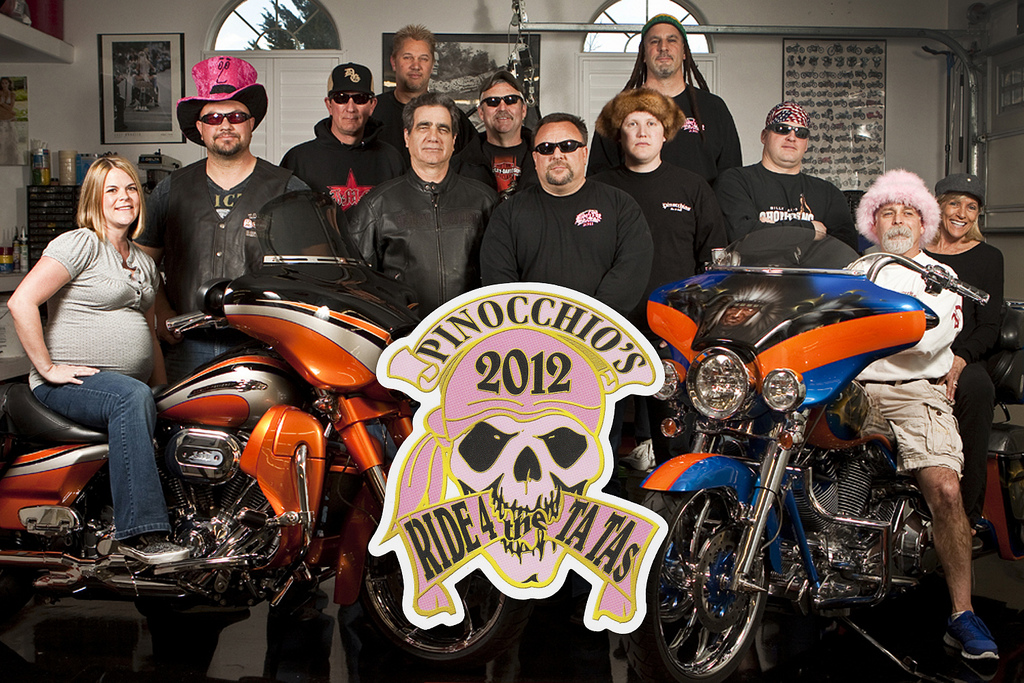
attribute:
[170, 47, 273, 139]
hat — Pink 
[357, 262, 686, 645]
skull — sign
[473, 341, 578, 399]
2012 — year, sign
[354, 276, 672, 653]
skull — pink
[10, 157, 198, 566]
lady — pregnant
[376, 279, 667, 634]
sign — pink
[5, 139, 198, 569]
woman — pregnant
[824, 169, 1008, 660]
man — older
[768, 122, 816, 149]
sun glasses — black colored